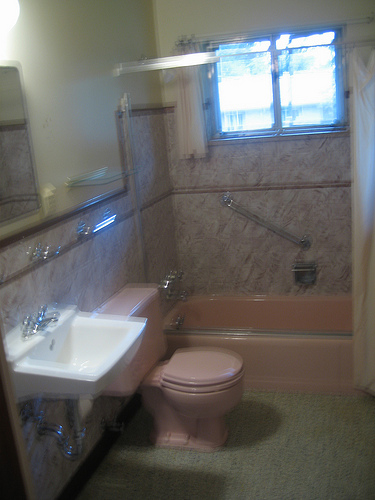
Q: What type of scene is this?
A: Indoor.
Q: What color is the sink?
A: White.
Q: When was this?
A: Daytime.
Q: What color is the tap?
A: Silver.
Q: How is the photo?
A: Blurred.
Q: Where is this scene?
A: Bathroom.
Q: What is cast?
A: Shadow.